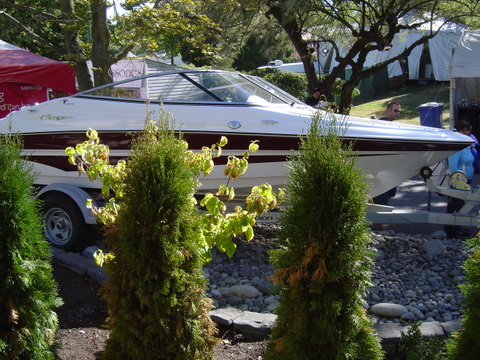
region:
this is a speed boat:
[6, 40, 477, 282]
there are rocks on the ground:
[174, 227, 477, 331]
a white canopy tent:
[443, 25, 478, 90]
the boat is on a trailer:
[4, 59, 479, 279]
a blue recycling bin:
[409, 92, 462, 137]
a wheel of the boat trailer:
[28, 184, 103, 262]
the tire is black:
[29, 193, 93, 250]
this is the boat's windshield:
[116, 61, 308, 111]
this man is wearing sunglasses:
[370, 85, 419, 139]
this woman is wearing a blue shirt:
[444, 119, 476, 185]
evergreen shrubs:
[0, 110, 476, 355]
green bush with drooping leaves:
[64, 128, 280, 324]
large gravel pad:
[25, 195, 476, 339]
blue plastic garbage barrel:
[415, 99, 442, 123]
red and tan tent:
[0, 35, 75, 115]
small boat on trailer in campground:
[0, 64, 473, 252]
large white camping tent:
[343, 6, 476, 74]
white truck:
[256, 57, 314, 71]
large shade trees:
[0, 0, 479, 113]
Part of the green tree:
[307, 167, 332, 212]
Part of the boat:
[238, 120, 279, 139]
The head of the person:
[383, 100, 402, 122]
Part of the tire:
[50, 196, 65, 207]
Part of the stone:
[382, 305, 391, 312]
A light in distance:
[320, 45, 331, 54]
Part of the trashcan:
[433, 114, 440, 123]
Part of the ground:
[406, 187, 414, 200]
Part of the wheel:
[53, 226, 59, 233]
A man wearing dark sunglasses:
[379, 94, 401, 123]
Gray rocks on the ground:
[391, 240, 471, 306]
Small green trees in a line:
[10, 118, 398, 358]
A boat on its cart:
[3, 59, 478, 248]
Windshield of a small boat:
[73, 61, 315, 112]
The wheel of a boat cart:
[36, 187, 99, 256]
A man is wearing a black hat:
[310, 83, 319, 100]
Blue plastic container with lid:
[414, 99, 448, 129]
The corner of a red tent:
[1, 25, 76, 134]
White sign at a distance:
[75, 57, 161, 96]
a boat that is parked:
[12, 36, 449, 240]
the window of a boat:
[163, 68, 275, 107]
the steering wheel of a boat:
[224, 76, 255, 107]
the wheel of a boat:
[27, 184, 84, 245]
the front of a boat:
[388, 114, 477, 170]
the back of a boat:
[0, 101, 65, 206]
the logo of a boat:
[34, 105, 71, 136]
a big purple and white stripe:
[218, 114, 300, 168]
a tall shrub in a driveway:
[113, 123, 218, 357]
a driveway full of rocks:
[377, 239, 435, 308]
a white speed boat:
[19, 31, 475, 268]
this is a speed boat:
[11, 27, 478, 299]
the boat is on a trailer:
[16, 36, 475, 264]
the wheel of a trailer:
[27, 171, 97, 268]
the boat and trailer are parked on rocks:
[2, 35, 478, 327]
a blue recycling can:
[408, 85, 451, 149]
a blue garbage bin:
[415, 87, 452, 159]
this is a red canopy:
[6, 27, 95, 108]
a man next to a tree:
[301, 70, 331, 105]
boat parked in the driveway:
[5, 49, 469, 244]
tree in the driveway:
[92, 116, 221, 350]